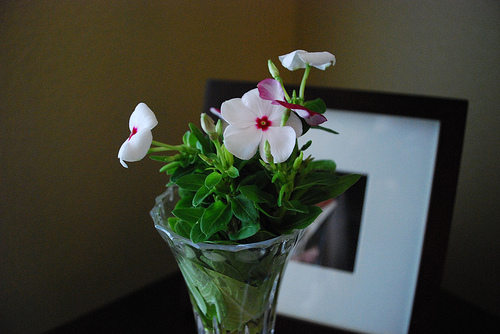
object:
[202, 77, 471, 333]
frame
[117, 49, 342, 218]
flower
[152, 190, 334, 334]
vase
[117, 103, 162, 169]
flower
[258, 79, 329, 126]
flowers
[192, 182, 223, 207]
leaf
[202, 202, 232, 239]
leaf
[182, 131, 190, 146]
leaf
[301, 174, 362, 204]
leaf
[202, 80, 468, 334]
picture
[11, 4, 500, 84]
background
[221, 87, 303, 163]
flower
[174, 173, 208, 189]
leaves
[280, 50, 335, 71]
flower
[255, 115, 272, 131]
center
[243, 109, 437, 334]
inset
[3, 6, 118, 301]
wall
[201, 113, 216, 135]
bud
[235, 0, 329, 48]
corner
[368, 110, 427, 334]
mat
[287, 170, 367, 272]
picture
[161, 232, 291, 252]
uneven edge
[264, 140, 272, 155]
bud